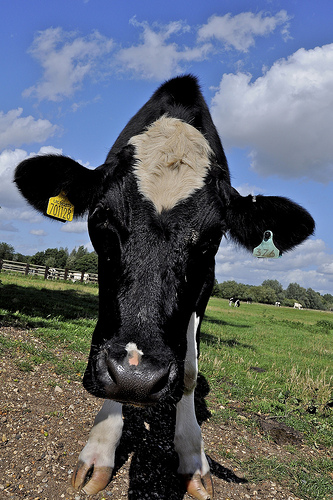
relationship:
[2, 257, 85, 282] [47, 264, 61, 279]
fence in front of cow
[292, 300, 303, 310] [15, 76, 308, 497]
white cow grazing behind cow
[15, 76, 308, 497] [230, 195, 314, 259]
cow on ear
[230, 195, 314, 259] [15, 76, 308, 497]
ear on cow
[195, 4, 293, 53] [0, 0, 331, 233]
clouds in sky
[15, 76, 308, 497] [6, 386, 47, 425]
cow looking at camera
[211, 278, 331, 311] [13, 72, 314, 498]
tree line behind cows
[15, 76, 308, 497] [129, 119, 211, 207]
cow has spot